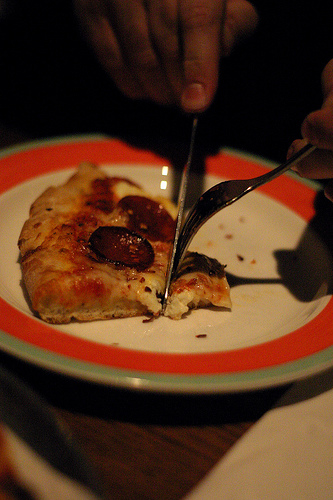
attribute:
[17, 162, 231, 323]
pizza — not whole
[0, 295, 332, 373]
stripe — orange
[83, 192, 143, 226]
pizza —  half eaten slice